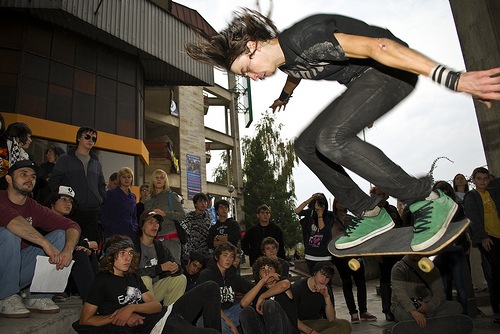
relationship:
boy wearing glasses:
[48, 127, 106, 245] [81, 132, 99, 142]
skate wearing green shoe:
[331, 214, 468, 269] [344, 196, 391, 249]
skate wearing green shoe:
[331, 214, 468, 269] [408, 185, 457, 247]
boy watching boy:
[195, 240, 246, 329] [290, 267, 342, 330]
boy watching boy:
[290, 267, 342, 330] [195, 240, 246, 329]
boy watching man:
[290, 267, 342, 330] [174, 0, 500, 252]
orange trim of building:
[3, 109, 149, 166] [0, 0, 253, 233]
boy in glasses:
[62, 124, 110, 216] [80, 130, 97, 140]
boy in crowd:
[62, 124, 110, 216] [5, 117, 495, 332]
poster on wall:
[174, 139, 224, 247] [176, 83, 206, 220]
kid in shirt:
[458, 164, 498, 316] [473, 188, 498, 235]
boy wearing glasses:
[48, 127, 106, 245] [84, 134, 97, 142]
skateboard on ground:
[390, 313, 474, 332] [327, 280, 390, 332]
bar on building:
[0, 111, 151, 164] [0, 0, 253, 233]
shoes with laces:
[345, 196, 456, 251] [411, 203, 441, 235]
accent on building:
[0, 113, 152, 166] [0, 0, 253, 233]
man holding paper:
[2, 159, 76, 319] [36, 253, 69, 295]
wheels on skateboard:
[344, 254, 434, 276] [321, 216, 475, 260]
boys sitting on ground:
[71, 185, 489, 307] [99, 276, 499, 332]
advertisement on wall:
[184, 152, 205, 198] [179, 81, 206, 195]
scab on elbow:
[373, 42, 388, 58] [377, 35, 394, 64]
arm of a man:
[323, 33, 498, 101] [174, 0, 500, 252]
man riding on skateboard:
[174, 0, 500, 252] [329, 218, 470, 272]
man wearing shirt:
[0, 160, 82, 318] [4, 190, 69, 245]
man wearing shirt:
[174, 0, 500, 252] [268, 28, 422, 90]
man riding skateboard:
[198, 7, 498, 244] [329, 218, 470, 272]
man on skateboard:
[198, 7, 498, 244] [329, 218, 470, 272]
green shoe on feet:
[334, 207, 396, 250] [337, 171, 499, 258]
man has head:
[174, 0, 500, 252] [225, 33, 276, 83]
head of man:
[225, 33, 276, 83] [174, 0, 500, 252]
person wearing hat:
[79, 230, 162, 332] [104, 234, 134, 257]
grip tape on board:
[376, 237, 411, 251] [328, 215, 476, 275]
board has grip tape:
[328, 215, 476, 275] [376, 237, 411, 251]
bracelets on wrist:
[430, 62, 458, 89] [446, 65, 460, 95]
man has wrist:
[178, 12, 463, 281] [446, 65, 460, 95]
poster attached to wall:
[186, 153, 203, 200] [178, 84, 208, 155]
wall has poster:
[178, 84, 208, 155] [186, 153, 203, 200]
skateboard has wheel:
[329, 218, 470, 272] [345, 256, 360, 274]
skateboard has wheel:
[329, 218, 470, 272] [418, 257, 435, 274]